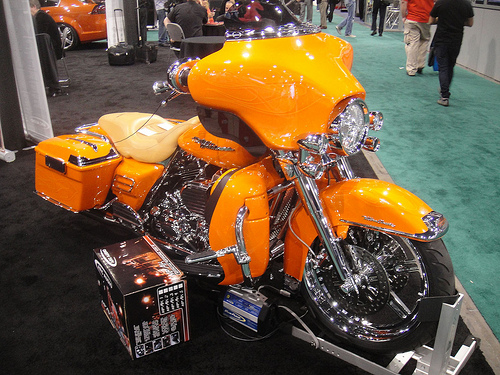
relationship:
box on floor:
[92, 239, 183, 369] [25, 269, 97, 348]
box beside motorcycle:
[92, 239, 183, 369] [36, 24, 463, 361]